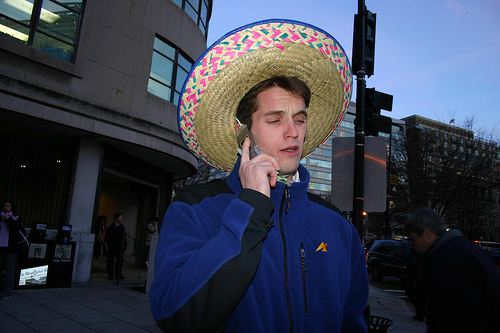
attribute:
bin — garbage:
[367, 312, 394, 331]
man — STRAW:
[147, 18, 372, 330]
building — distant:
[396, 114, 498, 204]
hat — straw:
[175, 19, 354, 174]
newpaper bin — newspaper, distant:
[19, 216, 56, 294]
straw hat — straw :
[175, 18, 353, 175]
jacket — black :
[109, 204, 160, 256]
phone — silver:
[229, 121, 264, 159]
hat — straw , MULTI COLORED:
[178, 12, 351, 169]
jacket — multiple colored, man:
[147, 159, 380, 331]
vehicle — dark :
[364, 236, 416, 283]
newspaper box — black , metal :
[43, 217, 80, 287]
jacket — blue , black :
[170, 192, 347, 284]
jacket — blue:
[147, 185, 359, 326]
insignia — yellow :
[308, 234, 332, 256]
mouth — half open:
[276, 133, 313, 160]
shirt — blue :
[146, 152, 376, 330]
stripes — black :
[151, 164, 360, 327]